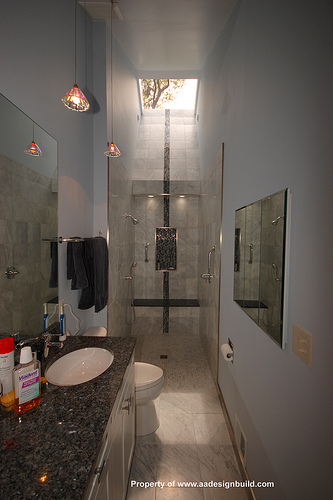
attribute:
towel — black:
[77, 232, 111, 314]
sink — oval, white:
[47, 334, 111, 393]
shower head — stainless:
[124, 212, 138, 225]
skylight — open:
[131, 65, 206, 126]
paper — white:
[208, 345, 234, 363]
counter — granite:
[16, 409, 94, 487]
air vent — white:
[289, 291, 322, 388]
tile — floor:
[157, 412, 195, 444]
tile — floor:
[192, 412, 232, 445]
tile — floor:
[154, 442, 201, 486]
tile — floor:
[129, 442, 157, 481]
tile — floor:
[196, 443, 247, 486]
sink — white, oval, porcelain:
[39, 329, 124, 396]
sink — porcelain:
[46, 344, 114, 388]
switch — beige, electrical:
[290, 322, 314, 366]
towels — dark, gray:
[39, 210, 126, 325]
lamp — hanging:
[59, 6, 93, 111]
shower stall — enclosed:
[116, 65, 220, 387]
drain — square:
[158, 352, 167, 361]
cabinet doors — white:
[110, 415, 131, 470]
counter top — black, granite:
[3, 321, 164, 485]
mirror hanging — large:
[3, 215, 52, 286]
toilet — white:
[137, 362, 169, 439]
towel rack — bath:
[58, 234, 83, 243]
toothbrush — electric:
[56, 297, 70, 344]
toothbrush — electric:
[37, 297, 52, 344]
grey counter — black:
[75, 334, 134, 354]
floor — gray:
[134, 332, 248, 496]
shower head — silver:
[124, 211, 139, 225]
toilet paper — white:
[218, 342, 236, 362]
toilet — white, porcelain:
[79, 323, 164, 439]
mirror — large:
[233, 188, 284, 335]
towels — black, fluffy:
[62, 230, 112, 313]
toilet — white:
[131, 356, 169, 437]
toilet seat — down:
[134, 359, 164, 391]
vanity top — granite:
[3, 332, 135, 495]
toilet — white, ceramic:
[136, 360, 164, 439]